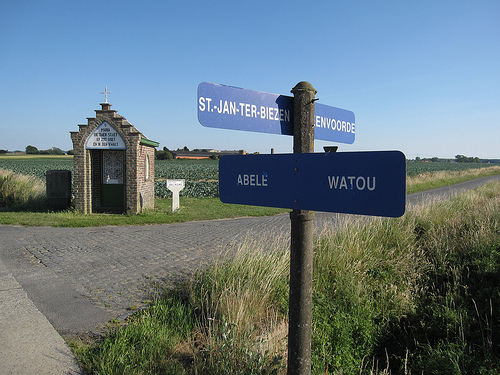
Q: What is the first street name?
A: St. Jan Ter Biezen Envoorde.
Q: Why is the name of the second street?
A: Abele Watou.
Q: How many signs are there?
A: Two.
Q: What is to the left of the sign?
A: Little Building.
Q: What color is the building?
A: Brown.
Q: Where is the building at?
A: Grassy field.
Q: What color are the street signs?
A: Blue.